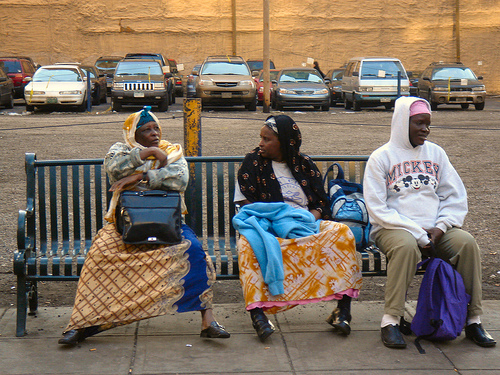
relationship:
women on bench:
[93, 101, 476, 323] [8, 147, 101, 276]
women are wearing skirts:
[93, 101, 476, 323] [59, 233, 385, 333]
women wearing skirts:
[93, 101, 476, 323] [59, 233, 385, 333]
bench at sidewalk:
[8, 147, 101, 276] [27, 344, 409, 371]